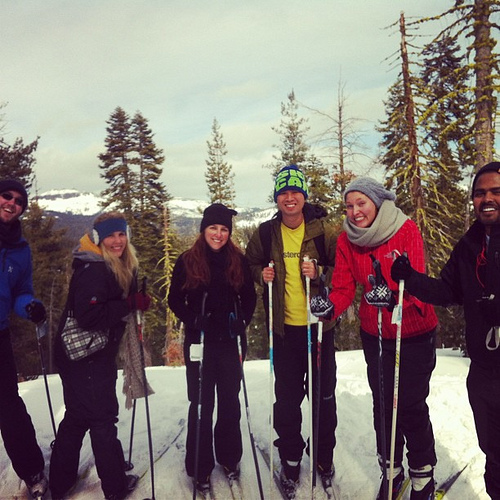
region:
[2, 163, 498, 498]
People on ski's on the snow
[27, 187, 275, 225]
Snowy mountain in the back ground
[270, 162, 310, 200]
Blue bonnet worn by a person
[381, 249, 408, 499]
Ski pole carried by a person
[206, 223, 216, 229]
right eye of the person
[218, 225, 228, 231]
left eye of the person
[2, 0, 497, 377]
Forest of trees in the background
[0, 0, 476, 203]
Cloudy weather in the sky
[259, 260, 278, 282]
left hand of a person carrying a ski pole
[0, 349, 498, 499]
The snowy mountainous region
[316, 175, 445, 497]
The smiling skater wearing a red top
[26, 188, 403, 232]
The snow peaked mountains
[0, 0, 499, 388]
The tall vegetated background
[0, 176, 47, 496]
The person wearing a blue jacket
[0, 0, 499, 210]
An overcast filled sky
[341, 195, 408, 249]
A gray head scarf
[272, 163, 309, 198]
A patterned knit cap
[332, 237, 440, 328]
the sweater is red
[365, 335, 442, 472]
the pants are black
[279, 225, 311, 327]
the tshirt is yellow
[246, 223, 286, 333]
the jacket is brown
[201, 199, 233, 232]
the marvin is black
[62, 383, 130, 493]
the pants are black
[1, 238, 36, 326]
the jacket is blue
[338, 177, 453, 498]
the woman is smiling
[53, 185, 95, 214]
snow is on the hill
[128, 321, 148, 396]
the scarf is brown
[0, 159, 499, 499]
A group of six skiers.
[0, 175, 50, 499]
A man wearing a blue coat.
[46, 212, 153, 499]
A woman wearing a blue headband.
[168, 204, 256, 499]
A woman dressed is black.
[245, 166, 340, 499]
A man wearing a yellow shirt.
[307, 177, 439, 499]
A woman wearing a red coat.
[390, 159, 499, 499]
A man dressed in black.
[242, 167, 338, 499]
A man wearing a dark blue hat with green lettering.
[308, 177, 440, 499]
A woman wearing a gray hat.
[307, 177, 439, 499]
A woman wearing a scarf around her neck.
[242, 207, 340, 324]
teenager has a yellow shirt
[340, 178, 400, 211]
girl has a gray hat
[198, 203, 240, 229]
girl is wearing a black hat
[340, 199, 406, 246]
girl has a grey scarf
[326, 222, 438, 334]
girl is wearing a red jacket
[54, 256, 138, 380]
girl is wearing a black jacket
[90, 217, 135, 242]
girl is wearing a blue ear warmer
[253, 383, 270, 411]
the snow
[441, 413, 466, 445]
sunlight on the snow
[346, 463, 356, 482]
the snow is white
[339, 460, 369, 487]
the white snow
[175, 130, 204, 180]
clouds in the sky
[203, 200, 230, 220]
a black beanie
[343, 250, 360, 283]
a red sweater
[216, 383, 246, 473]
the women is wearing pants